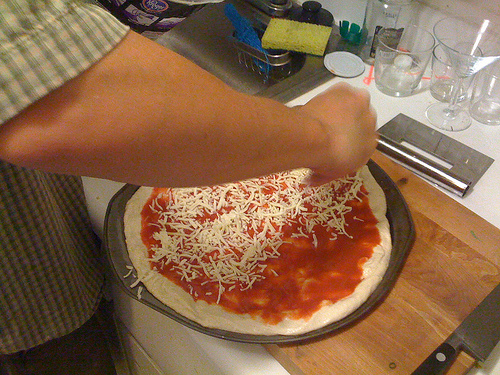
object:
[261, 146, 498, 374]
board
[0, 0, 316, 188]
arm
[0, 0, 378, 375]
man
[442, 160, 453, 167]
ground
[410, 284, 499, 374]
knife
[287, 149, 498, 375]
chopping block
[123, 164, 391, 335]
cheese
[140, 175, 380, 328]
pizza sauce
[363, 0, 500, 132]
container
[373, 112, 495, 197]
chopper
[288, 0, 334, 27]
sink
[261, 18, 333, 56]
sponge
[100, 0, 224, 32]
stopper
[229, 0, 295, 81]
sponge holder